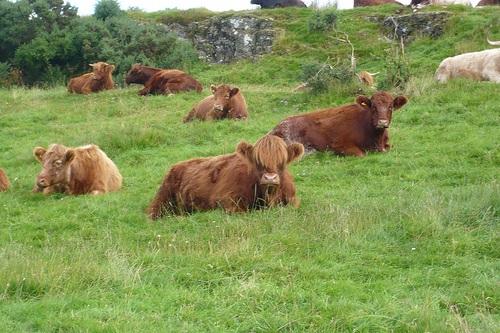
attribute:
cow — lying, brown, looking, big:
[147, 134, 304, 220]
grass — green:
[0, 1, 499, 330]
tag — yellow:
[359, 101, 368, 108]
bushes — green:
[1, 0, 212, 90]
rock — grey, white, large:
[157, 13, 281, 66]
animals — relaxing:
[0, 33, 500, 222]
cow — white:
[436, 33, 500, 85]